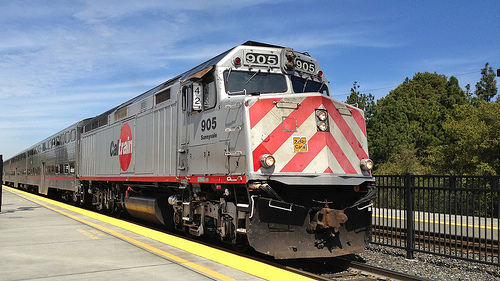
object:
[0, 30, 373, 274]
train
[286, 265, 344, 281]
tracks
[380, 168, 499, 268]
fence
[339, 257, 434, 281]
tracks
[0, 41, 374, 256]
locomotive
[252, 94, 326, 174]
stripes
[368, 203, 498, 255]
highway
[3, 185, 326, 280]
stripe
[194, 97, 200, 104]
number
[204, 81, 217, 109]
mirror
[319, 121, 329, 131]
headlight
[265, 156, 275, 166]
headlight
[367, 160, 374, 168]
headlight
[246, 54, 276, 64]
number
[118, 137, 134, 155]
word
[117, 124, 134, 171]
circle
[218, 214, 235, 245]
wheel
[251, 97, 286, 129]
stripes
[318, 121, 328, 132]
headlight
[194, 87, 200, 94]
number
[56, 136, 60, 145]
window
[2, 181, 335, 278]
platform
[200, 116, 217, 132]
number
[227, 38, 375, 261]
train front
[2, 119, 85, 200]
cars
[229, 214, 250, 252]
wheels